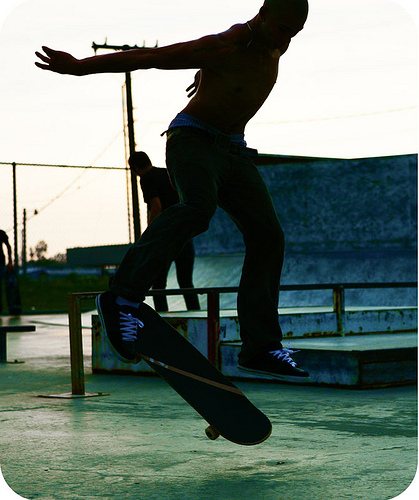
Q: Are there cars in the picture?
A: No, there are no cars.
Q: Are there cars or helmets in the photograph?
A: No, there are no cars or helmets.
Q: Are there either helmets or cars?
A: No, there are no cars or helmets.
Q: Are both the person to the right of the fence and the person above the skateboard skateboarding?
A: Yes, both the person and the person are skateboarding.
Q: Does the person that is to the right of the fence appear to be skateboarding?
A: Yes, the person is skateboarding.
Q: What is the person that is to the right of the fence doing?
A: The person is skateboarding.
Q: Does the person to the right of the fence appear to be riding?
A: No, the person is skateboarding.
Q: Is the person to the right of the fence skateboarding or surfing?
A: The person is skateboarding.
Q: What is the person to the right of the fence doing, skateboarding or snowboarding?
A: The person is skateboarding.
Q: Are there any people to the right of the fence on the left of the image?
A: Yes, there is a person to the right of the fence.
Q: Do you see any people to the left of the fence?
A: No, the person is to the right of the fence.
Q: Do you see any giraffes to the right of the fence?
A: No, there is a person to the right of the fence.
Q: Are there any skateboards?
A: Yes, there is a skateboard.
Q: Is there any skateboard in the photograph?
A: Yes, there is a skateboard.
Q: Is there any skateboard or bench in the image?
A: Yes, there is a skateboard.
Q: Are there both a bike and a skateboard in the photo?
A: No, there is a skateboard but no bikes.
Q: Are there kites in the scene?
A: No, there are no kites.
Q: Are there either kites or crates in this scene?
A: No, there are no kites or crates.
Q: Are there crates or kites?
A: No, there are no kites or crates.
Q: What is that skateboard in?
A: The skateboard is in the air.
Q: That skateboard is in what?
A: The skateboard is in the air.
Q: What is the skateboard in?
A: The skateboard is in the air.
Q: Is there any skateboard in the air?
A: Yes, there is a skateboard in the air.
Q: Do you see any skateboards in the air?
A: Yes, there is a skateboard in the air.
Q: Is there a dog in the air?
A: No, there is a skateboard in the air.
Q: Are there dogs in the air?
A: No, there is a skateboard in the air.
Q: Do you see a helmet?
A: No, there are no helmets.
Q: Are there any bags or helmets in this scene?
A: No, there are no helmets or bags.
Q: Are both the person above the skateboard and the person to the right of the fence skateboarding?
A: Yes, both the person and the person are skateboarding.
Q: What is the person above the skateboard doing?
A: The person is skateboarding.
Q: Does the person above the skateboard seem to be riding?
A: No, the person is skateboarding.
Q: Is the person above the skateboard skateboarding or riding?
A: The person is skateboarding.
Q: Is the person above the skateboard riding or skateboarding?
A: The person is skateboarding.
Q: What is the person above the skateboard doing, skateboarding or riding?
A: The person is skateboarding.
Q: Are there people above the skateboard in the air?
A: Yes, there is a person above the skateboard.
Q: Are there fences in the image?
A: Yes, there is a fence.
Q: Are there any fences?
A: Yes, there is a fence.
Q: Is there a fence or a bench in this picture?
A: Yes, there is a fence.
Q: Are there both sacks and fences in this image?
A: No, there is a fence but no sacks.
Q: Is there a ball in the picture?
A: No, there are no balls.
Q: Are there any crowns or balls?
A: No, there are no balls or crowns.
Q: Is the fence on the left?
A: Yes, the fence is on the left of the image.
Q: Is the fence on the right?
A: No, the fence is on the left of the image.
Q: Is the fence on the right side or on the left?
A: The fence is on the left of the image.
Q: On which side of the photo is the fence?
A: The fence is on the left of the image.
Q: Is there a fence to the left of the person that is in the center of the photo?
A: Yes, there is a fence to the left of the person.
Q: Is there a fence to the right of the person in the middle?
A: No, the fence is to the left of the person.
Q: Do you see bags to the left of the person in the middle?
A: No, there is a fence to the left of the person.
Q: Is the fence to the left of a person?
A: Yes, the fence is to the left of a person.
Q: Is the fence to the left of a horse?
A: No, the fence is to the left of a person.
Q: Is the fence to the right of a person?
A: No, the fence is to the left of a person.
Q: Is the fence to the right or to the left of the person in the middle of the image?
A: The fence is to the left of the person.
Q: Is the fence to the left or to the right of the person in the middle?
A: The fence is to the left of the person.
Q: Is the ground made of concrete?
A: Yes, the ground is made of concrete.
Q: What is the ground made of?
A: The ground is made of concrete.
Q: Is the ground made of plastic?
A: No, the ground is made of concrete.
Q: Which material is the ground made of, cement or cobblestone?
A: The ground is made of cement.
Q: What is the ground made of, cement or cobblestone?
A: The ground is made of cement.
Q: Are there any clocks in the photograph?
A: No, there are no clocks.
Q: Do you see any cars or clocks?
A: No, there are no clocks or cars.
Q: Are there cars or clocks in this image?
A: No, there are no clocks or cars.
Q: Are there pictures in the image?
A: No, there are no pictures.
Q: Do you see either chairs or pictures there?
A: No, there are no pictures or chairs.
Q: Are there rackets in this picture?
A: No, there are no rackets.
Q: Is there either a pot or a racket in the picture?
A: No, there are no rackets or pots.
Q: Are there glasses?
A: No, there are no glasses.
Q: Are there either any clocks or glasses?
A: No, there are no glasses or clocks.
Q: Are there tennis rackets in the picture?
A: No, there are no tennis rackets.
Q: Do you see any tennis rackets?
A: No, there are no tennis rackets.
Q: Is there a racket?
A: No, there are no rackets.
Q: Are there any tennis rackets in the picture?
A: No, there are no tennis rackets.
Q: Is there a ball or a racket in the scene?
A: No, there are no rackets or balls.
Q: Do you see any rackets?
A: No, there are no rackets.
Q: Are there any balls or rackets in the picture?
A: No, there are no rackets or balls.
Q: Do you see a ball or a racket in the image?
A: No, there are no rackets or balls.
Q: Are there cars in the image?
A: No, there are no cars.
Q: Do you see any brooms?
A: No, there are no brooms.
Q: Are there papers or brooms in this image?
A: No, there are no brooms or papers.